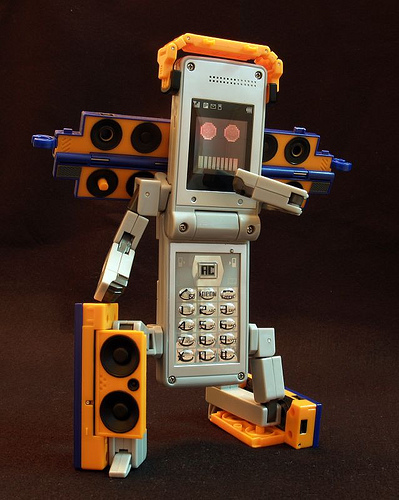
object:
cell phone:
[155, 54, 267, 387]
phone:
[154, 53, 269, 389]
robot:
[28, 33, 352, 477]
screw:
[187, 62, 194, 72]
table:
[0, 314, 399, 500]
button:
[178, 288, 235, 363]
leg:
[72, 302, 161, 476]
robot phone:
[31, 31, 352, 478]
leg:
[206, 322, 320, 450]